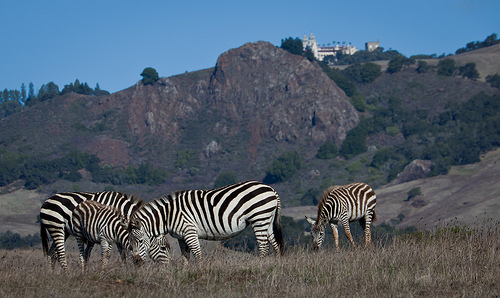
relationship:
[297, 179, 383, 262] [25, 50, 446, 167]
zebra standing boulders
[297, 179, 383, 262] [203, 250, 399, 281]
zebra eating grass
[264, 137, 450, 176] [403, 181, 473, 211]
bushes growing dirt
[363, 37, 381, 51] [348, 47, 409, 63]
building hidden by bushes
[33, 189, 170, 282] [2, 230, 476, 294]
zebra eating grass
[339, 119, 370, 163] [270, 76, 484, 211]
bush on hill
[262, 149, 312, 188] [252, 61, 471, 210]
bush on hill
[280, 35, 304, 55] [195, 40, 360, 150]
bush on boulder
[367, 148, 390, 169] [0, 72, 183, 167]
bush on boulders